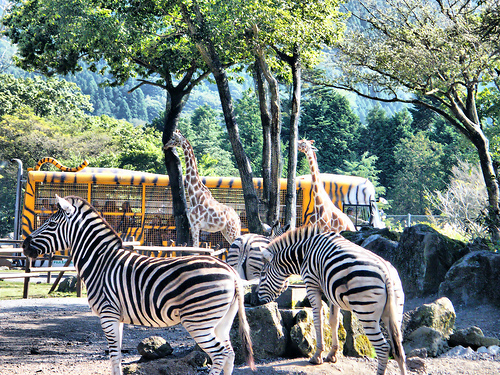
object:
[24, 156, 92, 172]
snake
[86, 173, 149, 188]
stripes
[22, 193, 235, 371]
zebra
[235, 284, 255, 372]
tail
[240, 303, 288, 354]
rocks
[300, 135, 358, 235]
giraffe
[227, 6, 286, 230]
tree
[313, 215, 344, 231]
spots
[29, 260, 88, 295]
fence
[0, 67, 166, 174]
trees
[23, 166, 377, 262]
bus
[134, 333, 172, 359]
rock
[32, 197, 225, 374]
stripes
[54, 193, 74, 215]
ear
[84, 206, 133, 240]
mane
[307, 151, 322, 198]
neck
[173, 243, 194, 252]
trunk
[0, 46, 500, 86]
leaves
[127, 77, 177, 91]
branch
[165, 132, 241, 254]
giraffes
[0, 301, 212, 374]
shadow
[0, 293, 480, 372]
ground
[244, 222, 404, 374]
animals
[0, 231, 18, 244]
pipe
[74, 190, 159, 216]
people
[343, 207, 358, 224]
driver